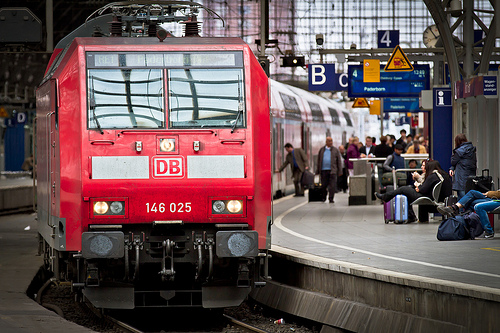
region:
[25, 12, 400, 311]
the train is red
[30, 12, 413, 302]
this is a passenger train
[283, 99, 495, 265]
people on the train platform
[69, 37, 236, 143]
front window of train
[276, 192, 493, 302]
white line on platform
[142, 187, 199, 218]
the numbers are white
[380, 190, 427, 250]
the luggage on platform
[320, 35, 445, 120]
the signs are hanging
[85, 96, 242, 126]
wipers on the widshield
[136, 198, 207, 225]
the numbers on the train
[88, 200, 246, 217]
headlights on the train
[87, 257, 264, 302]
gears under the train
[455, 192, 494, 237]
the legs are crossed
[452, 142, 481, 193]
the jacket is blue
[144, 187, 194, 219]
The number to the front of the train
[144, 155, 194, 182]
The letters to the front of the train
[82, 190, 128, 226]
The left head light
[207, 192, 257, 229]
The right headlight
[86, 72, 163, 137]
The left windshield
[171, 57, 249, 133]
The right windshield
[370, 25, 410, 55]
The sign with the number 4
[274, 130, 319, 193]
The man leaning on the train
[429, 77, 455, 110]
The sign with the letter i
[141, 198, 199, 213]
identifying numbers on the train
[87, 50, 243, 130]
windshield of the train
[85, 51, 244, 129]
reflections in the windshields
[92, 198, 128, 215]
a pair of headlights on the train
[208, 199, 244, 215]
a pair of headlights on the train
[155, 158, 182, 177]
a logo on the train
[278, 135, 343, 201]
passengers on the platform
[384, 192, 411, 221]
luggage on the platform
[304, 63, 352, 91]
letters on overhead signs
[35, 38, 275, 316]
red engine on the train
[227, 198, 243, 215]
Headlight of a train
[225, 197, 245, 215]
Headlight of a red train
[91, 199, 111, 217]
Headlight of a train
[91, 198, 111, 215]
Headlight of a red train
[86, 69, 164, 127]
Window of a train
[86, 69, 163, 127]
Window of a red train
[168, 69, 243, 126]
Window of a train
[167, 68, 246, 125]
Window of a red train